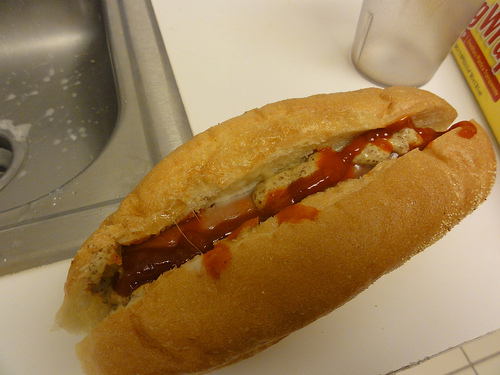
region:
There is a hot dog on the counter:
[90, 71, 490, 352]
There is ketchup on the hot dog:
[87, 110, 473, 312]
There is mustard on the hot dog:
[62, 41, 472, 344]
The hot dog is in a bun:
[102, 102, 476, 352]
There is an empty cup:
[333, 1, 451, 87]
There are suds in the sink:
[2, 47, 171, 262]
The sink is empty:
[1, 11, 119, 245]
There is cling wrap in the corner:
[447, 2, 496, 129]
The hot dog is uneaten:
[115, 62, 494, 347]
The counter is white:
[58, 1, 498, 367]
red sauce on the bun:
[201, 248, 240, 276]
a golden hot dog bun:
[250, 236, 368, 301]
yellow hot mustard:
[367, 147, 383, 161]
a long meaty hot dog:
[207, 205, 239, 217]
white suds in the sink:
[9, 113, 30, 139]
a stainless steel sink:
[21, 82, 135, 184]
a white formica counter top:
[217, 25, 302, 74]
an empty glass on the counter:
[366, 2, 460, 79]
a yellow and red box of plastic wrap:
[471, 38, 498, 93]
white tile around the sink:
[443, 343, 483, 373]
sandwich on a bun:
[54, 100, 475, 358]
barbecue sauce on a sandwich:
[133, 232, 198, 264]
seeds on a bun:
[433, 177, 488, 240]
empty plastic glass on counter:
[344, 0, 473, 86]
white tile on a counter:
[426, 354, 496, 369]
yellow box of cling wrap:
[462, 7, 499, 102]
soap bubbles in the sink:
[16, 70, 93, 168]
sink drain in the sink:
[2, 125, 32, 182]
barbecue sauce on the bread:
[195, 241, 236, 283]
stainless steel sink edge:
[113, 20, 221, 75]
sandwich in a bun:
[90, 76, 463, 357]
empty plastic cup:
[342, 0, 470, 93]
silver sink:
[25, 27, 195, 254]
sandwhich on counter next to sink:
[58, 53, 372, 368]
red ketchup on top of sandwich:
[120, 108, 474, 310]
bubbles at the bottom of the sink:
[12, 51, 87, 172]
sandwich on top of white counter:
[72, 53, 482, 361]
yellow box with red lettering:
[456, 8, 498, 146]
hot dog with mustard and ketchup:
[80, 74, 462, 358]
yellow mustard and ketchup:
[248, 156, 316, 203]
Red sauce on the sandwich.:
[293, 163, 420, 233]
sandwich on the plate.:
[72, 97, 354, 339]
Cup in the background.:
[332, 12, 497, 150]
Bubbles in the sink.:
[18, 43, 108, 159]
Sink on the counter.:
[20, 21, 318, 322]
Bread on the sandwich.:
[120, 187, 307, 338]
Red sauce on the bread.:
[74, 200, 376, 337]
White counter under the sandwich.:
[304, 285, 416, 348]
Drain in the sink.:
[4, 108, 41, 224]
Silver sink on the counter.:
[61, 42, 346, 202]